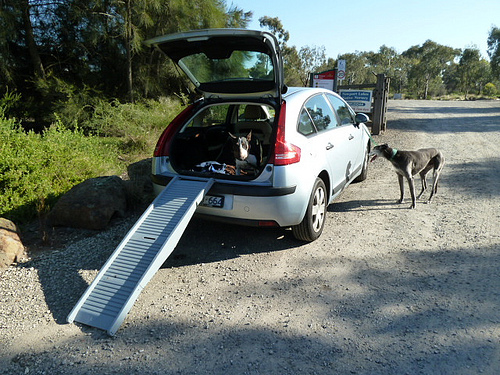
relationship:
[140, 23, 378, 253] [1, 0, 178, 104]
car near trees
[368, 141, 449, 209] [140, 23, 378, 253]
dog next   to car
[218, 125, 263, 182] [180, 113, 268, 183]
dog sitting back trunk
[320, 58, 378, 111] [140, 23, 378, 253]
signs in front car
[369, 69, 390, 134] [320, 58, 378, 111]
post supporting signs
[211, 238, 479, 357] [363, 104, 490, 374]
shadow along road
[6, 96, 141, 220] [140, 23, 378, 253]
shrubs next to car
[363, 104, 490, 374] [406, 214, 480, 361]
road has gravel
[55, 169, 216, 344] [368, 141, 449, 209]
ladder for dog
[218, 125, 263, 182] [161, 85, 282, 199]
dog on back car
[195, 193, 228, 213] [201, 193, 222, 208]
license plate has number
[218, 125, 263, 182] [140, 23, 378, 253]
dog on back car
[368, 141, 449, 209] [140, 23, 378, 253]
dog beside car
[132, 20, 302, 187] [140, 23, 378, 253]
hatch of car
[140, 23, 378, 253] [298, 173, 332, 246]
car has tire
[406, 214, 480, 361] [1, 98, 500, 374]
gravel on road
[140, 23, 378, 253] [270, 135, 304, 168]
car has taillight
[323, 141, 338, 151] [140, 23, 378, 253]
handle on car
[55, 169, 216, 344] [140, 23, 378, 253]
ramp on back car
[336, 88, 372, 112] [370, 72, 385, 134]
signs on post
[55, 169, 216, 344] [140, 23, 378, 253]
ramp into car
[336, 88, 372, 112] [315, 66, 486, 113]
signs on entrance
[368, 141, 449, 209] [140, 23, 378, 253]
dog next white car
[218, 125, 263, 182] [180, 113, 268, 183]
dog in trunk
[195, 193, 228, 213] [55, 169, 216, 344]
license plate under ramp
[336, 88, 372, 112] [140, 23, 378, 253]
signs front of car